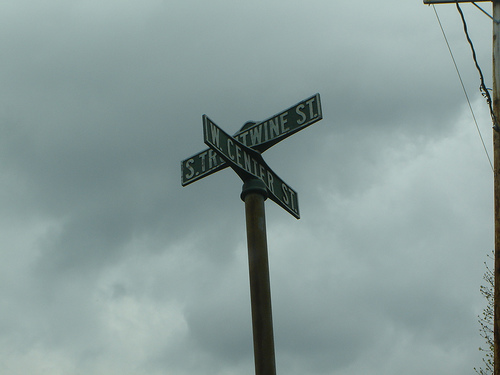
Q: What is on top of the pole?
A: Green street signs.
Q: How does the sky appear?
A: Cloudy and overcast.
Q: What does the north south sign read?
A: Center st.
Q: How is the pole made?
A: Of metal.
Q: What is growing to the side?
A: A tree.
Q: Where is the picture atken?
A: A street corner.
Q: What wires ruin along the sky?
A: Electrical.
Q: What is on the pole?
A: Street signs.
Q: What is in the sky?
A: Clouds.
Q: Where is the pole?
A: On the street.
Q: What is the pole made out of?
A: Metal.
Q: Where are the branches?
A: On the right.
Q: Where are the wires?
A: Top right.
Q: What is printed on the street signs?
A: Street names.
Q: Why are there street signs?
A: To show street names.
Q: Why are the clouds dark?
A: It might rain.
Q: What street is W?
A: Center.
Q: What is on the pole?
A: Signs.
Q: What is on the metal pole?
A: Signs.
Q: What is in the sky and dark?
A: Clouds.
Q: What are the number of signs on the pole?
A: Two.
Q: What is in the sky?
A: Clouds.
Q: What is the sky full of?
A: Clouds.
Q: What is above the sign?
A: Sky.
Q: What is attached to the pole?
A: Wires.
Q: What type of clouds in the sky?
A: Dark.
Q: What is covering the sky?
A: Clouds.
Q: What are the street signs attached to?
A: Pole.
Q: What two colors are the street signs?
A: Green and white.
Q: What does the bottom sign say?
A: W. CENTER ST.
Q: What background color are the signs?
A: Green.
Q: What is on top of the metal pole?
A: Two street signs.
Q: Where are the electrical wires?
A: On the right near the wooden pole.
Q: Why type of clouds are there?
A: Grey storm clouds.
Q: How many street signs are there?
A: Two.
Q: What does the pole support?
A: Street signs.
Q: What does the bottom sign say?
A: W. CENTER ST.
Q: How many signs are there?
A: 2.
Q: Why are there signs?
A: To tell the street names.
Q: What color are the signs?
A: Green.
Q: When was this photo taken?
A: During the day.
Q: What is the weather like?
A: Cloudy.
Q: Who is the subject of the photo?
A: The sign.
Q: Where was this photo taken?
A: Corner of center st and trentwine.